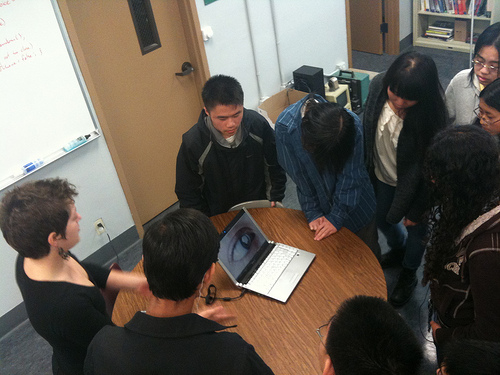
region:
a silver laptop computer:
[215, 207, 314, 302]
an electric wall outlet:
[92, 217, 104, 236]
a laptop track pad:
[280, 269, 296, 284]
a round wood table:
[109, 198, 386, 373]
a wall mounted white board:
[0, 0, 101, 194]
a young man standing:
[175, 74, 285, 220]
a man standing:
[81, 208, 275, 373]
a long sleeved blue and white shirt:
[278, 100, 370, 227]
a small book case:
[409, 0, 498, 52]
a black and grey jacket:
[170, 112, 285, 209]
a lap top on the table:
[203, 191, 326, 293]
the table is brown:
[235, 223, 360, 275]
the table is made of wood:
[223, 280, 308, 360]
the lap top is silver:
[217, 207, 313, 297]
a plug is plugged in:
[88, 209, 121, 256]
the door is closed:
[70, 1, 200, 108]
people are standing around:
[162, 30, 498, 202]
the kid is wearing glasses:
[459, 35, 497, 78]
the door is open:
[337, 2, 407, 84]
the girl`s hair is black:
[349, 35, 446, 116]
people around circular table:
[13, 80, 440, 353]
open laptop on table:
[215, 203, 309, 316]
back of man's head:
[133, 210, 210, 302]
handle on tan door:
[165, 53, 202, 86]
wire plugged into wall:
[91, 215, 120, 247]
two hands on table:
[305, 207, 337, 249]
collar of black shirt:
[121, 305, 238, 348]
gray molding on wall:
[93, 219, 143, 269]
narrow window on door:
[122, 4, 171, 68]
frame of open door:
[336, 6, 394, 73]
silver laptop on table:
[218, 224, 318, 305]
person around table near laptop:
[11, 173, 131, 328]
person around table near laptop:
[118, 210, 236, 370]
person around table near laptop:
[187, 79, 285, 198]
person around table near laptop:
[305, 300, 392, 372]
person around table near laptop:
[287, 90, 362, 227]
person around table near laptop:
[361, 73, 445, 253]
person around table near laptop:
[410, 126, 497, 301]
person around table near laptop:
[473, 80, 498, 133]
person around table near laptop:
[445, 22, 492, 119]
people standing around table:
[50, 7, 495, 367]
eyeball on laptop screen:
[221, 213, 266, 280]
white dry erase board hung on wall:
[20, 11, 97, 182]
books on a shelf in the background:
[396, 0, 479, 49]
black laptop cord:
[199, 283, 256, 310]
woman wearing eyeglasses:
[462, 42, 496, 87]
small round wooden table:
[133, 186, 388, 360]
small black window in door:
[124, 7, 181, 67]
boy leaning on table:
[302, 98, 356, 233]